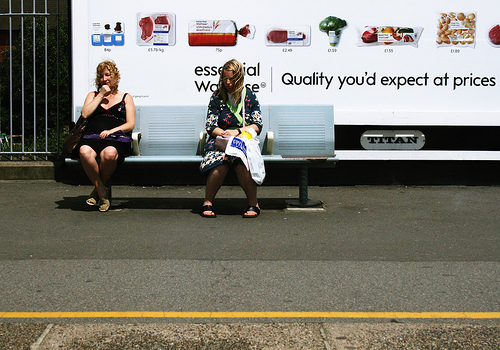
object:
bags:
[236, 128, 266, 185]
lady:
[79, 60, 135, 212]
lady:
[200, 59, 263, 218]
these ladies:
[79, 58, 262, 218]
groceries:
[91, 12, 500, 54]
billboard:
[91, 12, 500, 94]